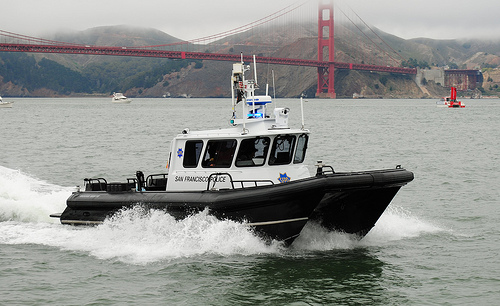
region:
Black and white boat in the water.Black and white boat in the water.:
[173, 155, 186, 261]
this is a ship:
[12, 39, 427, 273]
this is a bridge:
[0, 31, 405, 95]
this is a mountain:
[155, 6, 427, 147]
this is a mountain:
[44, 19, 171, 94]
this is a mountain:
[421, 28, 491, 88]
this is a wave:
[14, 178, 99, 253]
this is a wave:
[105, 202, 155, 257]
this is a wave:
[187, 211, 252, 263]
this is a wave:
[302, 208, 360, 272]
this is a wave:
[5, 163, 60, 241]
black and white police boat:
[55, 59, 414, 250]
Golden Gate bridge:
[3, 5, 415, 97]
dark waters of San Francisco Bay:
[1, 97, 498, 302]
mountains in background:
[9, 26, 499, 99]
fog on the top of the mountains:
[7, 11, 498, 56]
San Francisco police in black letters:
[171, 175, 228, 185]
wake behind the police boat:
[1, 165, 68, 240]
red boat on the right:
[437, 88, 464, 108]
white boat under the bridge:
[110, 90, 132, 104]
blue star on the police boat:
[276, 172, 291, 186]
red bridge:
[11, 26, 489, 87]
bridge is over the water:
[13, 13, 477, 99]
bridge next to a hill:
[271, 19, 377, 97]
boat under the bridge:
[95, 75, 131, 104]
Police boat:
[33, 86, 443, 280]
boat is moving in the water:
[51, 113, 405, 259]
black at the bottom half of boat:
[62, 166, 422, 278]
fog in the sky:
[33, 0, 481, 52]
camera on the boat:
[261, 104, 312, 137]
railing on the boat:
[197, 158, 292, 198]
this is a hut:
[436, 50, 478, 116]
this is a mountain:
[68, 20, 193, 128]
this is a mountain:
[403, 36, 497, 109]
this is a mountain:
[4, 32, 62, 107]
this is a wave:
[114, 210, 176, 270]